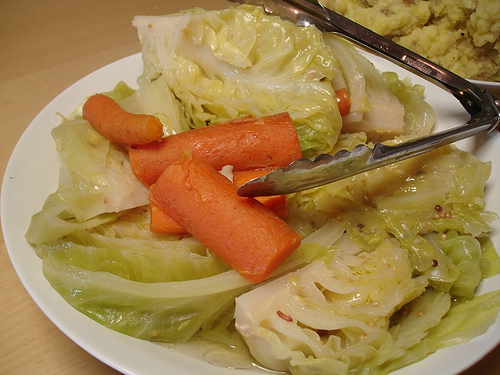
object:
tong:
[229, 0, 499, 198]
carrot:
[81, 92, 163, 144]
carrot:
[151, 170, 289, 233]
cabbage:
[132, 5, 343, 163]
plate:
[1, 43, 498, 374]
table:
[0, 0, 499, 373]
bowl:
[319, 0, 500, 77]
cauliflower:
[353, 1, 430, 34]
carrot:
[128, 111, 303, 187]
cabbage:
[233, 239, 425, 374]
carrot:
[148, 165, 301, 284]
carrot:
[335, 88, 352, 116]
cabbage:
[38, 221, 348, 344]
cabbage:
[374, 159, 500, 297]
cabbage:
[54, 76, 193, 221]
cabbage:
[321, 35, 436, 167]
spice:
[434, 205, 441, 213]